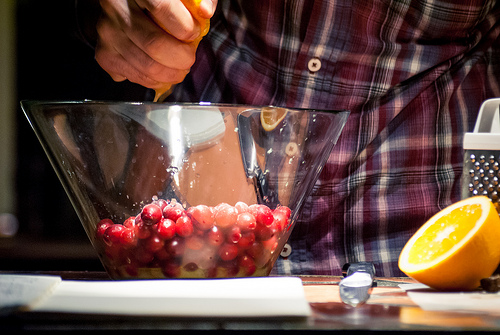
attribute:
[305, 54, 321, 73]
button — round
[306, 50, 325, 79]
button — white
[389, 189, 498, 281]
orange — cut , half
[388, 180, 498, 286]
orange — fruit 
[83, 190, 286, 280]
grapes — red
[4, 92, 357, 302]
bowl — clear 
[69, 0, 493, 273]
shirt — plaid 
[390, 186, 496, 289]
orange — half , sliced 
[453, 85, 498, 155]
handle — white 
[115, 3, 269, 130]
fruit — slice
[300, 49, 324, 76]
button — round 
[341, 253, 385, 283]
handle — black 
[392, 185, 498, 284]
half — cut half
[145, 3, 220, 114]
orange — squeezed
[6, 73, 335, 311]
mixing bowl — large, clear glass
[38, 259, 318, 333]
cutting board — white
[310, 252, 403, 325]
knife — clear, plastic handled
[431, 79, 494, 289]
grater — grey plastic, silver metal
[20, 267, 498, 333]
counter top — wooden, kitchen counter top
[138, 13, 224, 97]
orange jucie — fresh squeezed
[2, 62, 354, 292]
bowl — glass bowl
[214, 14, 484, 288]
shirt — plaid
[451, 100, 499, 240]
food grater — metal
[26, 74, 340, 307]
bowl — large, glass 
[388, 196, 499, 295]
orange — half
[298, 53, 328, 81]
button — tan, round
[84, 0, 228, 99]
hand — man's hand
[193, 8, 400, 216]
shirt — striped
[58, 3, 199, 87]
hand — right hand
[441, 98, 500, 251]
grater — cheese grater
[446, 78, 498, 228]
grater — cheese grater, white, silver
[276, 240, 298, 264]
button — bottom bost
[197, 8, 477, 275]
shirt — reddish purple, plaid patterned, plaid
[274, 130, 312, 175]
button — tan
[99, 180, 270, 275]
berries — red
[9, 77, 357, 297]
bowl — glass 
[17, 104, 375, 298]
bowl — clear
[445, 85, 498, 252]
grater — metal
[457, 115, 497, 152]
handle — white